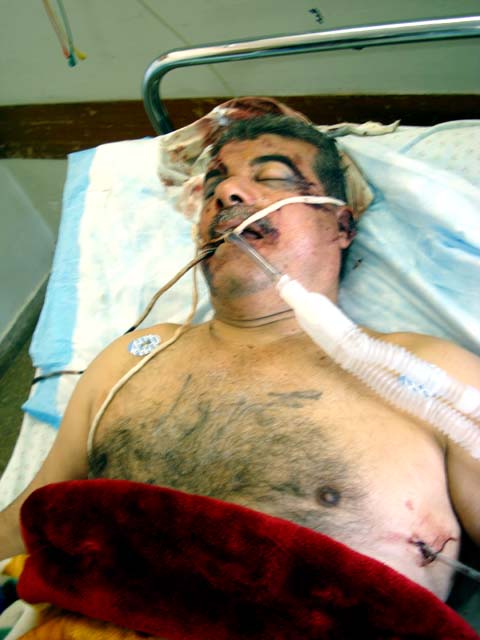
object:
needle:
[407, 523, 451, 571]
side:
[352, 421, 461, 604]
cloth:
[152, 95, 373, 221]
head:
[194, 114, 359, 313]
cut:
[294, 176, 316, 188]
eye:
[253, 164, 293, 189]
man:
[0, 110, 480, 626]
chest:
[81, 353, 405, 537]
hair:
[89, 366, 372, 555]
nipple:
[314, 484, 344, 509]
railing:
[126, 17, 479, 137]